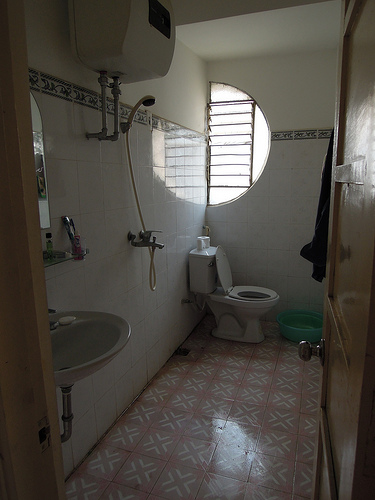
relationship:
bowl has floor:
[281, 300, 317, 344] [63, 319, 324, 496]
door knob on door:
[296, 332, 328, 364] [304, 6, 370, 492]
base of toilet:
[205, 321, 264, 349] [186, 244, 279, 344]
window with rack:
[207, 81, 271, 207] [203, 97, 257, 189]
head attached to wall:
[130, 93, 166, 118] [40, 27, 212, 410]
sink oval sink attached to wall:
[41, 289, 146, 394] [113, 293, 155, 357]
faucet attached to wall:
[125, 225, 176, 253] [63, 126, 207, 368]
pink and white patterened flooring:
[43, 453, 160, 464] [75, 447, 220, 500]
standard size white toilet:
[147, 298, 258, 397] [184, 234, 279, 347]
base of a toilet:
[219, 293, 274, 359] [57, 35, 370, 270]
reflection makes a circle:
[143, 74, 282, 215] [72, 414, 190, 490]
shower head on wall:
[99, 225, 182, 289] [96, 309, 143, 347]